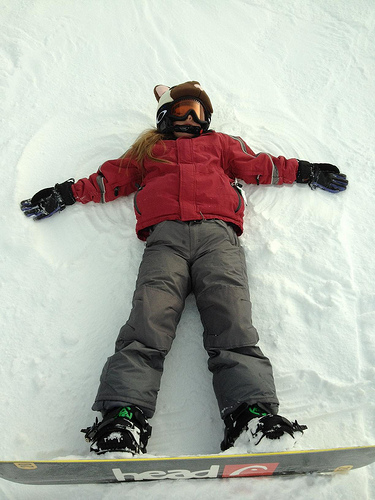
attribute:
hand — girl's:
[20, 174, 72, 236]